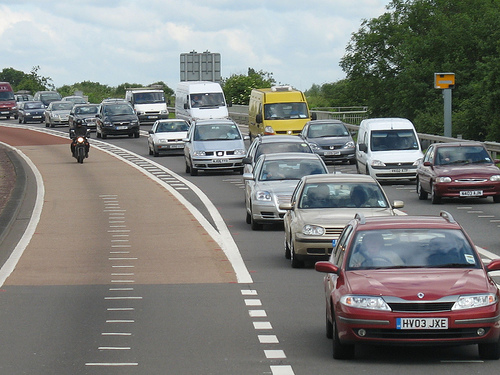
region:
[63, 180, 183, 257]
light on the ground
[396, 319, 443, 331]
license plate on the car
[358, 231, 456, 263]
the windshield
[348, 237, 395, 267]
driver of the car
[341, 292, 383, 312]
the headlight on the car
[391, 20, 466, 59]
the bush is green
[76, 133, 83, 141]
headlight on the motorcycle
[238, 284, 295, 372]
white dashes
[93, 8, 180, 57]
clouds in the sky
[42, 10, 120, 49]
the cloud is white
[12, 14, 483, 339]
A busy highway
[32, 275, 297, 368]
The road is made of pavement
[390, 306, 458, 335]
License plate HV03 JXE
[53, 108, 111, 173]
Person riding a motorcycle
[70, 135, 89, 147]
Motorcycle headlight is on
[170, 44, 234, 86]
The back of a highway sign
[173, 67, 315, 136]
Yellow van in front of a white van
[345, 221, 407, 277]
Person driving on the right side of the car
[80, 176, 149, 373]
White lines in the middle of the lane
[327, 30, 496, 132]
Green trees on the side of the road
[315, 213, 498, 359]
A burgundy car on the road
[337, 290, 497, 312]
Headlights on a burgundy car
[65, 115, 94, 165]
A motorcycle in the middle of the road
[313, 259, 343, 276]
Side mirror on a burgundy car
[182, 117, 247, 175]
A silver van in traffic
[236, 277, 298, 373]
A segmented line painted on the road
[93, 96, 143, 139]
A black van in traffic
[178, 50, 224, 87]
The back of a street sign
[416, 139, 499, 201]
A car driving on the highway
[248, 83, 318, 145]
A yellow van in traffic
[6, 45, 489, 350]
several cars traveling down a highway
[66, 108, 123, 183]
a motorcycle traveling down a highway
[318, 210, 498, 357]
a car traveling down a highway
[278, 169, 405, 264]
a car traveling down a highway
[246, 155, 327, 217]
a car traveling down a highway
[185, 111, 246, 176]
a van traveling down a highway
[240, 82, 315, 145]
a yellow van traveling down a highway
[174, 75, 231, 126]
a white van traveling down a highway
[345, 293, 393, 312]
the headlight of a car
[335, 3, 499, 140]
the foliage of trees beside the highway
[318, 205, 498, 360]
Red car on the road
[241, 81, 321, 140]
Yellow van on the road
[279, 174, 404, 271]
Car on the road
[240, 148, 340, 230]
Silver car on the road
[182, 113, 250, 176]
Van on the road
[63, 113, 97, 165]
Motorcycle on the road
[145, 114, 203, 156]
White car on the road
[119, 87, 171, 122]
White van on the road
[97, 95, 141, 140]
Black van on the road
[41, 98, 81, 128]
Silver car on the road